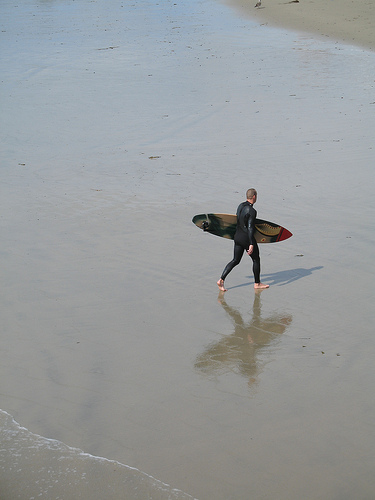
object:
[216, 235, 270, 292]
legs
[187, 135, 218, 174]
water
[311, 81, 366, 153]
sand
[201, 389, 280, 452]
sand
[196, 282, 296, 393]
reflection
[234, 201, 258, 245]
wetsuit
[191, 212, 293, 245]
surfboard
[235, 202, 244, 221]
left arm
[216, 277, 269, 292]
feet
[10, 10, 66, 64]
sand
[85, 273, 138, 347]
water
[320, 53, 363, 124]
water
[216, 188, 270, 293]
man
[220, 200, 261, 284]
suit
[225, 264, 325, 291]
shadow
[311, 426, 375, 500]
ground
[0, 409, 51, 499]
water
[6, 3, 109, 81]
area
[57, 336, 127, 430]
sand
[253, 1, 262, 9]
bird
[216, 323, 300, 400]
water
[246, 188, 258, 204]
head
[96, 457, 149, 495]
water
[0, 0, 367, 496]
sea shore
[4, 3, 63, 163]
water